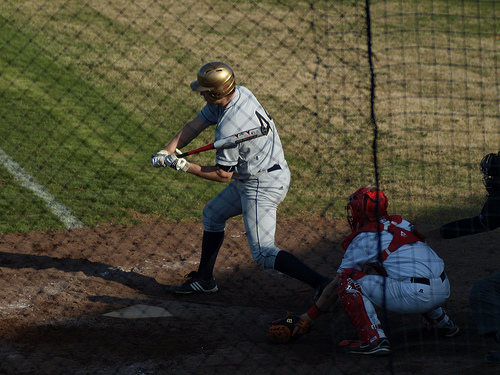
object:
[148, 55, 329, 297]
batter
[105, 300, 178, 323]
plate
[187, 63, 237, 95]
helmet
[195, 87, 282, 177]
shirt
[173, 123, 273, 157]
bat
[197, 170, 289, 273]
pants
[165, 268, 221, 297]
shoe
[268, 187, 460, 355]
catcher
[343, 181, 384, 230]
helmet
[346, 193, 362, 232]
guard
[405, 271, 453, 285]
belt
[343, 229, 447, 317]
outfit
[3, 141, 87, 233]
line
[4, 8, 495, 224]
grass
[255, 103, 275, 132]
44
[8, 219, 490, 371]
dirt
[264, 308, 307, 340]
mitt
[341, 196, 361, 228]
mask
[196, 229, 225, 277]
sock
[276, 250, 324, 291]
sock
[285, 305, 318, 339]
hand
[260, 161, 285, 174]
belt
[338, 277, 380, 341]
pads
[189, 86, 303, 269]
uniform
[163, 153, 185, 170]
gloves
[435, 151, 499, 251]
umpire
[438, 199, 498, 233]
jacket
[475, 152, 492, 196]
mask